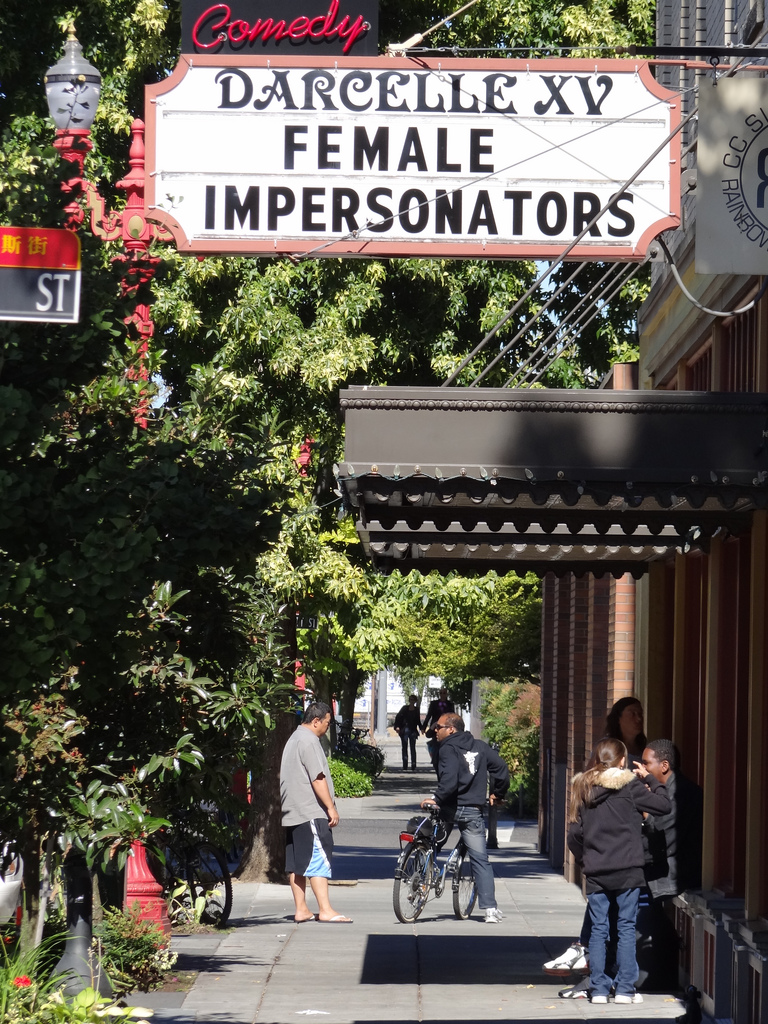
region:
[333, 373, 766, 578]
An awning on a building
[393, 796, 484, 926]
A bicycle on the sidewalk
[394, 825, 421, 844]
A red reflector on a bicycle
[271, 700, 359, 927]
A man standing on the sidewalk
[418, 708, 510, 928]
A man straddling a bicycle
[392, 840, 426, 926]
A tire on a bicycle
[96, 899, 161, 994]
A green plant next to the sidewalk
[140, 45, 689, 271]
A sign on a building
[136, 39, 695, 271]
white and red marquee with black letters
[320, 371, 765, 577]
black cloth awning with dagged hems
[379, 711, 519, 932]
man in black jacket on a bicycle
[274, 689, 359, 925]
man wearing black and white shorts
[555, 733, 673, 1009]
girl wearing black jacket with sheepskin hood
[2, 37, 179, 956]
red lamp post with street sign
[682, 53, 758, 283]
square white sign with black leters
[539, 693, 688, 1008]
family waiting in the shade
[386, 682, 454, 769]
couple holding hands walking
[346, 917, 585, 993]
shadow cast on the ground by awning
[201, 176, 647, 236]
black writing in all caps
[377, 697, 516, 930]
man standing over a bike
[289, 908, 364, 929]
a pair of sandals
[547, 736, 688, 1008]
man leaning on the building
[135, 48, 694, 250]
black writing on a white background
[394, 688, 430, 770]
silhouette of a person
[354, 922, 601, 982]
shadow on the ground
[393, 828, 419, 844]
red light on the back of the bike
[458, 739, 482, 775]
white design on the back of the jacket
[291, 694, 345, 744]
the head of a man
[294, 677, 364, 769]
the hair of a man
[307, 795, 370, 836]
the hand of a man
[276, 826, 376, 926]
the legs of a man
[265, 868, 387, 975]
the feet of a man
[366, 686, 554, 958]
a man on a bike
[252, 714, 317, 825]
the back of a man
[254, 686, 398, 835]
a man wearing a shirt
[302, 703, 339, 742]
the ear of a man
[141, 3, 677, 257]
Advertising board of a show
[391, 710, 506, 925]
A man with a cycle in front of a building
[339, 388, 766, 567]
The awning in front of a building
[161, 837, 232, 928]
A cycle parked under a tree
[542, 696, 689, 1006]
A group of people near the building wall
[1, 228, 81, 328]
Part of a signboard with the name of the street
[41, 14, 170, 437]
Outdoor lights and the lampposts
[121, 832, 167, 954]
Part of the red base of the lamppost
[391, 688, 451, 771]
A couple walking holding hands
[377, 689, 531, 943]
A man on a bicycle on the sidewalk.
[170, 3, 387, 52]
back and red comedy sign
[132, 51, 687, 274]
white theater sign with black lettering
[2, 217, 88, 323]
black and white street sign with red top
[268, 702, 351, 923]
man wearing gray shirt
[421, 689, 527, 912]
man holding bicycle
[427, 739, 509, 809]
navy blue sweatshirt with white pattern on back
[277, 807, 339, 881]
blue and black basketball shorts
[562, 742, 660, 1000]
woman wearing black jacket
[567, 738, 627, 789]
dark brown ponytail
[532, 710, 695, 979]
man leaning on side of building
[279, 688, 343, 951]
man wearing shorts and flip flops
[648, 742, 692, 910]
man sitting on a windowsill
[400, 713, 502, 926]
man standing with his bike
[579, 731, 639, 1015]
young woman in a black coat